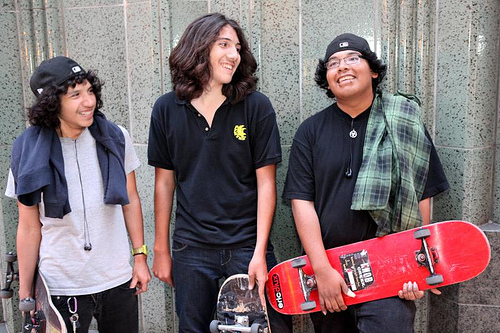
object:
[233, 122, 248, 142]
logo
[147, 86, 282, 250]
shirt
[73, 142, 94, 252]
ear buds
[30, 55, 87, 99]
baseball hat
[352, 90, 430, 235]
shirt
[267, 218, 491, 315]
skateboard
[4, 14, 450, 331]
boys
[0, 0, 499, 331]
wall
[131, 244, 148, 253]
watch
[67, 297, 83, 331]
car keys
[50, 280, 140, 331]
pants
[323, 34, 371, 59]
cap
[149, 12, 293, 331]
teen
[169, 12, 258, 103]
hair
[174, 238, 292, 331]
denim jeans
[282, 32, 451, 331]
boy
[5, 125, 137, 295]
shirt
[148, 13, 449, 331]
boys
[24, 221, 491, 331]
skateboards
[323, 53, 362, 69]
glasses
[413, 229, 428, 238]
wheel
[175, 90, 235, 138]
collar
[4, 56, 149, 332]
boy